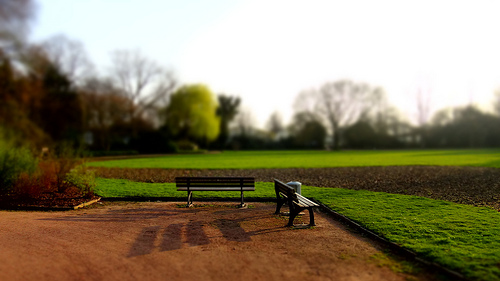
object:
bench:
[272, 177, 319, 226]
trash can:
[285, 179, 303, 198]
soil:
[95, 161, 493, 213]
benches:
[174, 176, 319, 227]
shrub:
[169, 85, 220, 148]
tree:
[33, 57, 94, 151]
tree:
[32, 25, 179, 157]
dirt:
[87, 163, 496, 209]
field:
[0, 201, 454, 281]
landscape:
[0, 0, 500, 281]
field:
[0, 150, 500, 281]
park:
[0, 93, 494, 279]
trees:
[0, 126, 38, 201]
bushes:
[0, 95, 95, 210]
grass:
[354, 196, 468, 241]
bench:
[174, 176, 254, 208]